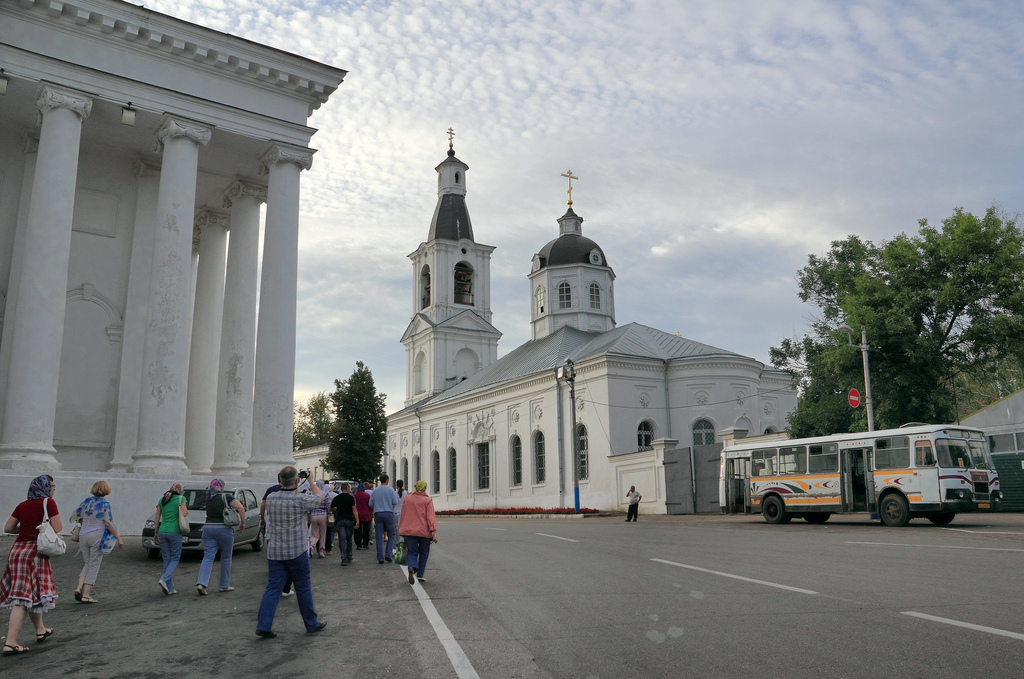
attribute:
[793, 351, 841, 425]
leaves — green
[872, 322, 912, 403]
leaves — green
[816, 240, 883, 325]
leaves — green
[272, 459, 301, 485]
head — man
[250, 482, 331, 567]
shirt — man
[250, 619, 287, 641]
foot — man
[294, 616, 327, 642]
foot — man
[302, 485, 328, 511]
elbow — man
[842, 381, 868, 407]
sign — red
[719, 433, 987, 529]
bus — yellow, white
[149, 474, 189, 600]
woman — walking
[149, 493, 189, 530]
shirt — green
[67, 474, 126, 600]
woman — older, walking, blue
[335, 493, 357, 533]
shirt — black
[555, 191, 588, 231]
steeple — small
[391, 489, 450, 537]
jacket — peach, windbreaker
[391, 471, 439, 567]
person — pink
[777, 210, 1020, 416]
leaves — green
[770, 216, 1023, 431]
leaves — green